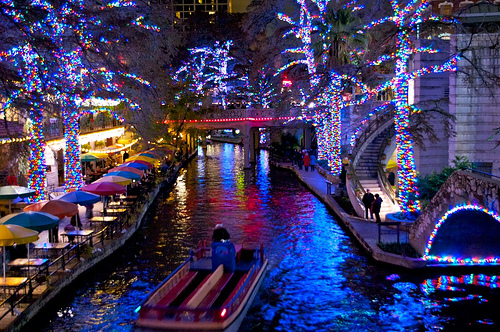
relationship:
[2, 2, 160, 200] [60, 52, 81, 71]
trees with lights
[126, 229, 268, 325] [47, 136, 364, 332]
boat on canal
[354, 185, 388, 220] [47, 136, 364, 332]
people next to canal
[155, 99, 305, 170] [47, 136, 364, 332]
bridge over canal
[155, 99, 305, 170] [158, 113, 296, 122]
bridge with light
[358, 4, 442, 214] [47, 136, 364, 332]
tree next to canal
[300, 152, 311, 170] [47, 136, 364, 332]
lady next to canal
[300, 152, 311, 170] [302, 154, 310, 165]
lady in coat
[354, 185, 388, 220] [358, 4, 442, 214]
people next to tree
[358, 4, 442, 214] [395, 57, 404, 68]
tree with lights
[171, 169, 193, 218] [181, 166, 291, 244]
reflection in water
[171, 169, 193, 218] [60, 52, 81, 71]
reflection of lights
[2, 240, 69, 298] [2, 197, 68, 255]
tables with umbrellas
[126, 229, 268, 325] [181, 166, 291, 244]
boat on water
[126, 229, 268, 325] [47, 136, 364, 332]
boat through canal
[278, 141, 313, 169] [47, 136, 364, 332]
people by canal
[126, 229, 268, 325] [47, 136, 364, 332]
boat in canal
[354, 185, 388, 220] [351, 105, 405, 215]
people at stairs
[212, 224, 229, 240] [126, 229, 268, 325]
person operating boat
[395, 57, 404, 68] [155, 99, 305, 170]
lights on bridge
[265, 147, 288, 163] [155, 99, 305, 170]
handrail near bridge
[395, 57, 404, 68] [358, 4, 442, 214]
lights on tree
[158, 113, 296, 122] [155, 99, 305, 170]
light underneath bridge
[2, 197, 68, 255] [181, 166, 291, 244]
umbrellas next to water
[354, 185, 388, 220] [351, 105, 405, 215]
people near stairs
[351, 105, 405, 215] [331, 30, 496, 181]
stairs on building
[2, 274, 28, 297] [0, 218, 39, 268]
table under umbrella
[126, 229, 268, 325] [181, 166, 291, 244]
boat in water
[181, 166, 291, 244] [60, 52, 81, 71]
water reflecting lights